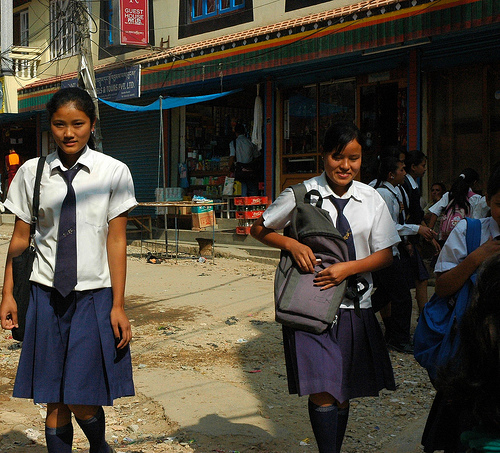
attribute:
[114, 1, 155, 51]
red sign — business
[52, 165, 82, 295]
tie — blue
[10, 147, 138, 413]
uniform — blue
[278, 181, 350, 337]
backpack — blue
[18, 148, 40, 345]
bag — black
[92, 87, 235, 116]
tarp — blue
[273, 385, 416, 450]
socks — blue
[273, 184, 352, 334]
grey bag — large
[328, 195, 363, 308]
tie — blue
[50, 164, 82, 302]
tie — blue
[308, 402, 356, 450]
socks — knee high, blue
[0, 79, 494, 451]
female students — crowd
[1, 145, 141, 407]
outfit — blue, white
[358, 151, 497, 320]
girls — crowd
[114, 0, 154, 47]
sign — red, white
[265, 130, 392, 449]
girl — wearing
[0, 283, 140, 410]
skirt — blue, pleated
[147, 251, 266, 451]
dirt — road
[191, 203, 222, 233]
box — cardboard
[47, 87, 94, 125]
hair — dark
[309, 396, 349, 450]
socks — blue 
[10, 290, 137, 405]
skirt — blue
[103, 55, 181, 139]
sign — blue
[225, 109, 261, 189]
person — standing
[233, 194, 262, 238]
bottled beverages — stacked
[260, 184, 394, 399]
outfit — white, blue 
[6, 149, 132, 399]
outfit — white, blue 